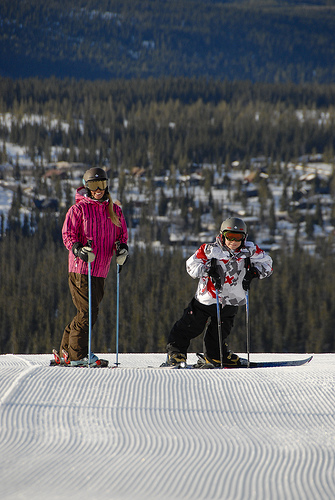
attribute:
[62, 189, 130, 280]
coat — white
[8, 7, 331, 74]
mountain — big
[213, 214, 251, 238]
helmet — brown